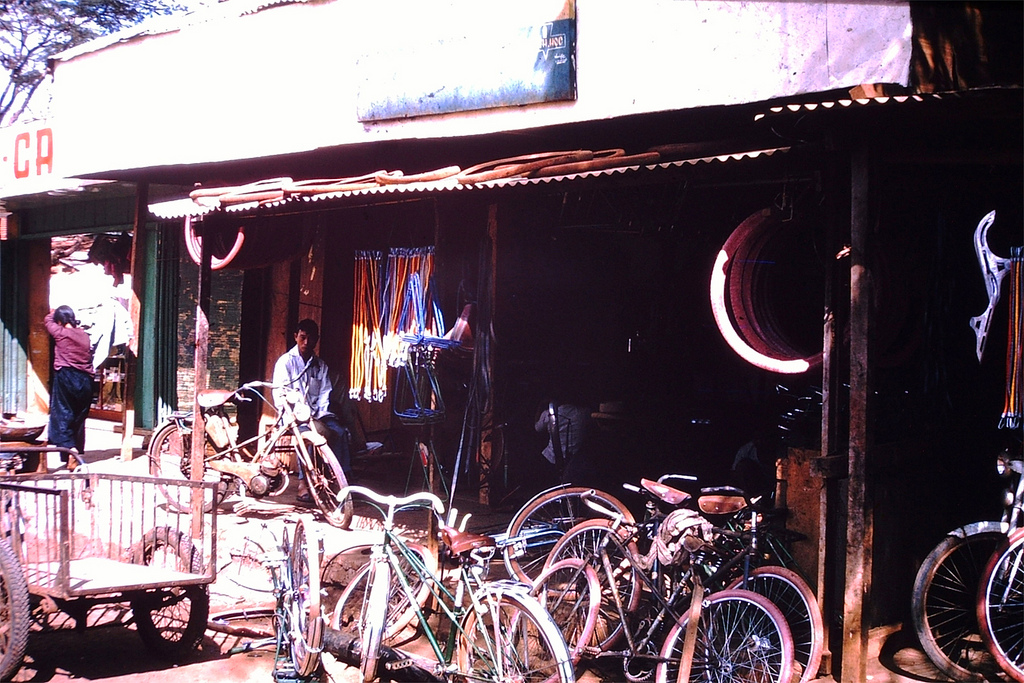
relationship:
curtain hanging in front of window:
[344, 266, 392, 400] [344, 243, 463, 395]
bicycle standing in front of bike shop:
[538, 484, 798, 679] [139, 94, 991, 676]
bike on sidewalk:
[145, 356, 351, 531] [21, 387, 415, 634]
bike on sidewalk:
[145, 356, 351, 531] [125, 359, 355, 574]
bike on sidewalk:
[123, 353, 361, 565] [13, 394, 433, 639]